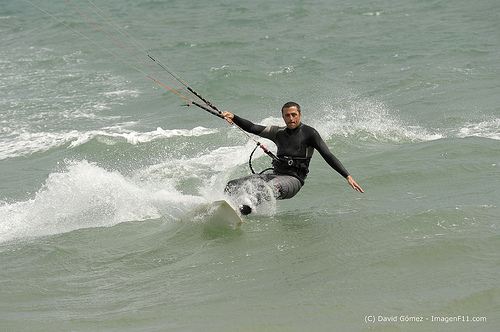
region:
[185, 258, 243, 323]
the water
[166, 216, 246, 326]
the water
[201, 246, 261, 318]
the water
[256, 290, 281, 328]
the water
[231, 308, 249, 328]
the water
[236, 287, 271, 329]
the water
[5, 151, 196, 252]
a large white breaking wave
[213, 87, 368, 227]
a man surfing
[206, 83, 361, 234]
a man parasailing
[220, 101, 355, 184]
a black wet suit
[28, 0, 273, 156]
a set of wires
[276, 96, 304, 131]
a man's face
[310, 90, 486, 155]
a white breaking wave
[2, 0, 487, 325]
a large body of water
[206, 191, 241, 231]
a white surf board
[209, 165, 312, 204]
a grey wet suit bottom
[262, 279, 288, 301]
the water is clear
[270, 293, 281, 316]
the water is clear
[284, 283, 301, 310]
the water is clear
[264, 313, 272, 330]
the water is clear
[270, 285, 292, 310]
the water is clear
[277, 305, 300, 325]
the water is clear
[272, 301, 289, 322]
the water is clear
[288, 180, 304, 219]
the water is clear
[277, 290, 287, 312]
the water is clear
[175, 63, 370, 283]
the man is parasailing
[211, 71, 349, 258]
he is wearing a wet suit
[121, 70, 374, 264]
the cords he is holding are black, red & clear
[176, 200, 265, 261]
the board is white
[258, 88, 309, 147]
the man has short hair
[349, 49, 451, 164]
the water is green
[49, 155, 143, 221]
the foam on the wake is white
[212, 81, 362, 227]
the top of his wet suit is balck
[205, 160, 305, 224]
the pants of the wet suit are grey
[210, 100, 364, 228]
a man in a black and gray wetsuit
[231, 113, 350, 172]
black long sleeve wet shirt on the surfer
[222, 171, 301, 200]
grey wet pants on the man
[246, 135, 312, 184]
a black waist belt connected to ropes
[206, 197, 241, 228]
the tip of a white surfboard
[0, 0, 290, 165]
ropes connected to the surfer and a kite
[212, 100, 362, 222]
man in black and grey surfing on the ocean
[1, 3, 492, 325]
ropes on a kite connected with ropes to the man's waist belt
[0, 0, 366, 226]
a surfer holding the ropes to a kite on a surfboard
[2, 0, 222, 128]
ropes from a kite